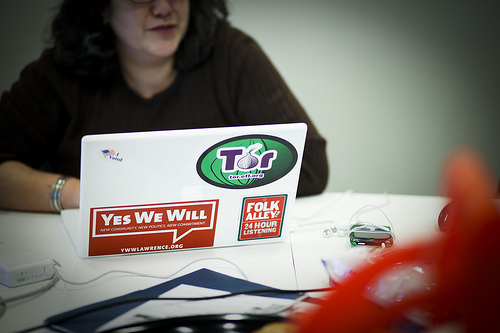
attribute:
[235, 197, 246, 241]
line — a part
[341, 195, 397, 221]
lien — part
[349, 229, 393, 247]
box — black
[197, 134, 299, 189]
sticker — green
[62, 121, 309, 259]
laptop — white, macbook, apple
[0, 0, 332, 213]
woman — working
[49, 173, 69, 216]
bracelet — silver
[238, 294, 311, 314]
wire — white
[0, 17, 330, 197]
shirt — long sleeved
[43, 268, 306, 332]
booklet — dark blue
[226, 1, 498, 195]
wall — white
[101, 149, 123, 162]
sticker — i voted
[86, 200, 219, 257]
sticker — orange, red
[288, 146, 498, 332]
item — orange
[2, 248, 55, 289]
brick — white